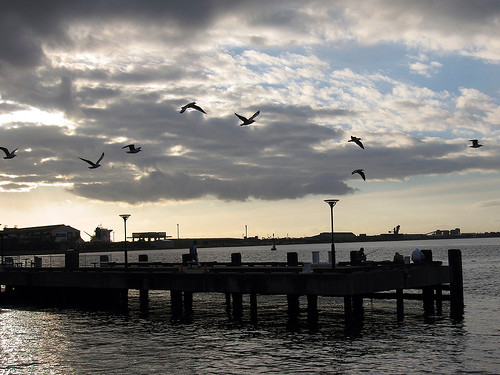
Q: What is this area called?
A: Pier.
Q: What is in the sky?
A: Clouds.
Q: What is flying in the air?
A: Birds.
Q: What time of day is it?
A: Dusk.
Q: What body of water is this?
A: Ocean.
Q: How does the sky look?
A: Partly cloudy.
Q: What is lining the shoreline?
A: Buildings.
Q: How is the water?
A: Calm.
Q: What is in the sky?
A: Birds.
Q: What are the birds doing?
A: Flying.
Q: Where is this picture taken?
A: At a lake.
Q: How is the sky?
A: Cloudy.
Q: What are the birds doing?
A: Flying away.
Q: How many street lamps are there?
A: Two.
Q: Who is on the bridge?
A: Two men.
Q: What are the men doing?
A: One is fishing and other is walking.